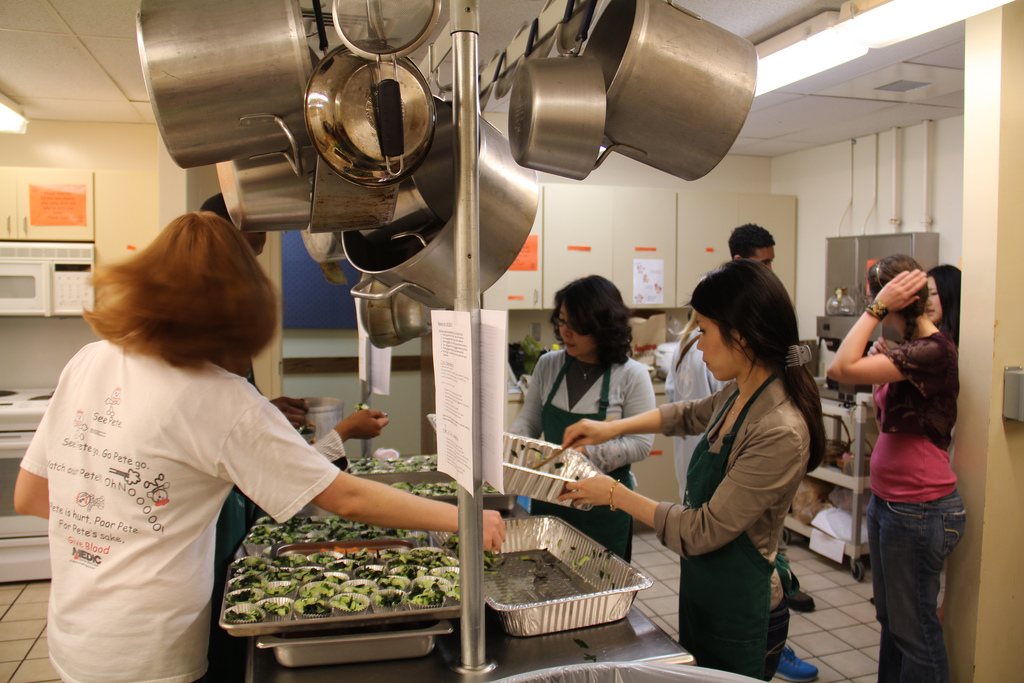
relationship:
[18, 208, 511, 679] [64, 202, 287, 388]
woman has hair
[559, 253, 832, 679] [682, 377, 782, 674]
girl wearing an apron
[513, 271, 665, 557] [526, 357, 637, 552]
girl wearing a apron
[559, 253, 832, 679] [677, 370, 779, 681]
girl wearing a apron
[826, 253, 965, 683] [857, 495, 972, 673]
girl wearing blue pants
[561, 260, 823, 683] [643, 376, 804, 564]
girl in shirt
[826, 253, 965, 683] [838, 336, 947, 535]
girl wearing shirt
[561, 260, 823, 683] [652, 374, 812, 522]
girl wearing apron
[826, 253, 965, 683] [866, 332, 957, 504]
girl wearing shirt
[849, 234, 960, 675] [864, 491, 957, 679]
girl wearing pants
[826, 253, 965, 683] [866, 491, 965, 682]
girl wearing blue pants